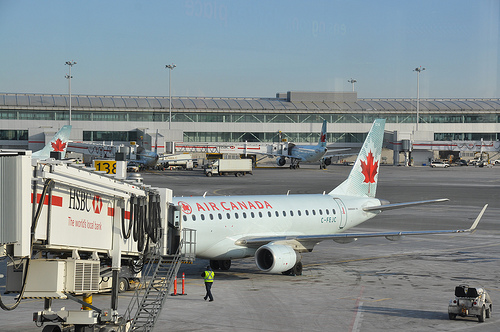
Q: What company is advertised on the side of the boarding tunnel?
A: HSBC.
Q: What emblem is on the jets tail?
A: Maple Leaf.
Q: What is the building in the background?
A: Airport terminal.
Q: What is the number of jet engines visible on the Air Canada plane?
A: 1.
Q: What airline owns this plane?
A: Air Canada.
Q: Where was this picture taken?
A: Airport.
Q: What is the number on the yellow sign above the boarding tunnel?
A: 138.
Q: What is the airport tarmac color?
A: Gray.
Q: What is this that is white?
A: Plane loading chute.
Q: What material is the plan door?
A: It is metal.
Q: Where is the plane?
A: The plane is on the terminal runway.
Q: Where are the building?
A: The building is part of the airport.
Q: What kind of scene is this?
A: Airport.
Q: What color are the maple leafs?
A: Red.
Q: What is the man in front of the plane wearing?
A: A yellow jacket.